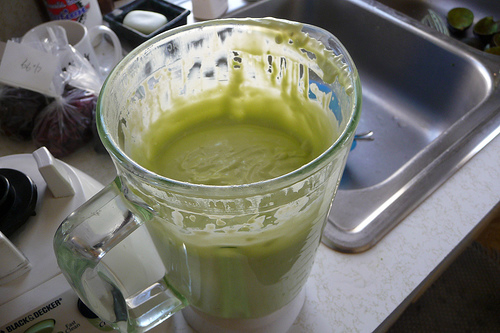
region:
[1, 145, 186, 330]
The bottom half to the blender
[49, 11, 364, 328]
The glass top to the blender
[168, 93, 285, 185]
The food on the blender is white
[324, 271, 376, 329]
The counter is the color white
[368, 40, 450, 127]
The sink is stainless steel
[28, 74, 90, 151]
A bag of food on the counter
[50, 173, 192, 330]
The handle of the blender top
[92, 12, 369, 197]
The shape of the blender is round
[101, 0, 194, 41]
The soap is in the dish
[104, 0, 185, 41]
The soap dish is the color black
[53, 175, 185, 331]
Clear handle of a blender.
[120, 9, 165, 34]
White bar of soap.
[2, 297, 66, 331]
The words BLACK & DECKER.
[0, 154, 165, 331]
A white base blender to the left of the blender.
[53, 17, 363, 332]
A clear and white based blender on the counter.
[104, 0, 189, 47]
A black soap holder up on the sink.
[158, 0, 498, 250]
Silver sink to the right of a blender.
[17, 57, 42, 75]
The numbers 4.99 on a white card.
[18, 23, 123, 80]
A white mug behind a white tag.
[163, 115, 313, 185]
The yellow paste inside a blender.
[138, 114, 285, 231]
green cream in the blender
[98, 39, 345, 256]
green cream in the blender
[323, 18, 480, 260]
sink made of steel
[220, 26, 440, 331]
sink made of steel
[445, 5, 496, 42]
Two avocado peels in sink.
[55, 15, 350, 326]
Pitcher of blender on counter.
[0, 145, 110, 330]
White blender base on counter.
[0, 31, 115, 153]
Three clear bags filled with dark red items.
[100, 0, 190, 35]
Black container holding soap.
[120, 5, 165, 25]
White bar of soap.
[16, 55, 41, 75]
'4.99' written in black.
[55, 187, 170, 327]
Glass handle to blender pitcher.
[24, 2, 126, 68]
Two white mugs on counter.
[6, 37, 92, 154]
Freezer food with label.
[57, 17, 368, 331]
Blender with avocado mixture.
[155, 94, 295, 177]
Blender avocado inside blender.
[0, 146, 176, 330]
White blender base on counter.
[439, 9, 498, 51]
Avocado skins in sink.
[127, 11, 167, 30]
Soap inside of black dish.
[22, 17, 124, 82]
White coffee mug on counter.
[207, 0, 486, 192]
Inside of metal sink.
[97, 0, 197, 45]
Soap dish on counter top.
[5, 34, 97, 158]
Red food in plastic bag.